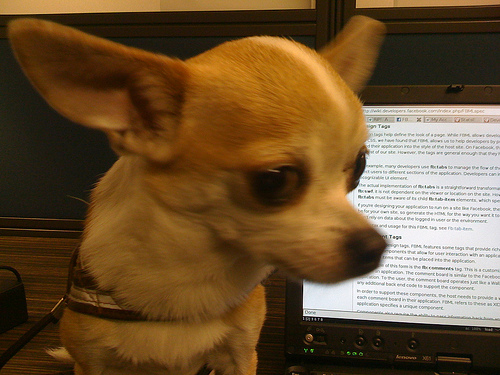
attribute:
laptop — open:
[266, 96, 499, 373]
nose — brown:
[338, 222, 390, 264]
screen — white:
[302, 101, 498, 326]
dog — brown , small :
[9, 0, 384, 371]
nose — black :
[344, 227, 388, 273]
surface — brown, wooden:
[0, 232, 287, 373]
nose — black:
[335, 218, 402, 280]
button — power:
[296, 331, 313, 348]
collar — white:
[20, 235, 253, 367]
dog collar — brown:
[40, 263, 170, 342]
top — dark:
[370, 81, 496, 106]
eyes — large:
[244, 152, 379, 202]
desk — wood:
[2, 227, 92, 374]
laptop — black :
[254, 34, 499, 329]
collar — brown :
[51, 266, 265, 331]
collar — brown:
[65, 257, 156, 321]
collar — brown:
[66, 239, 211, 327]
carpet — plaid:
[15, 231, 63, 285]